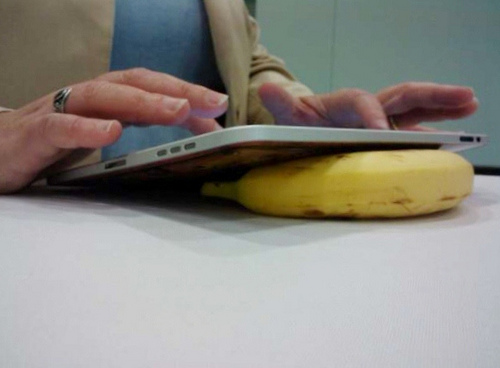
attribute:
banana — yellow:
[195, 146, 475, 220]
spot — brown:
[297, 207, 329, 217]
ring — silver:
[52, 86, 71, 113]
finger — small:
[49, 81, 193, 128]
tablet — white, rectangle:
[45, 119, 489, 196]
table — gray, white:
[1, 169, 500, 367]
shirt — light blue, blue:
[95, 0, 262, 160]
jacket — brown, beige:
[0, 1, 316, 177]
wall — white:
[243, 0, 499, 170]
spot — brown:
[337, 152, 351, 163]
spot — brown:
[391, 198, 413, 208]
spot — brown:
[438, 195, 456, 204]